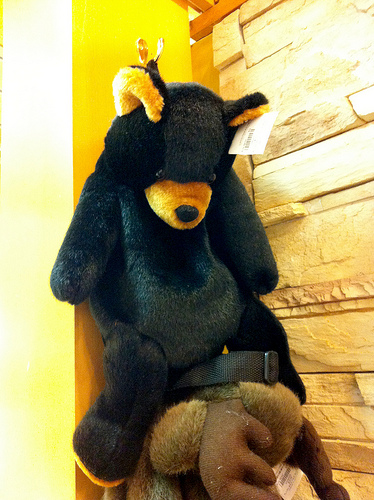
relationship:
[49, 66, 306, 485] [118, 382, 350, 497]
teddy bear on moose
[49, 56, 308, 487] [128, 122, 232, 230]
bear has face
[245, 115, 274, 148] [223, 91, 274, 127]
white tag hanging from ear